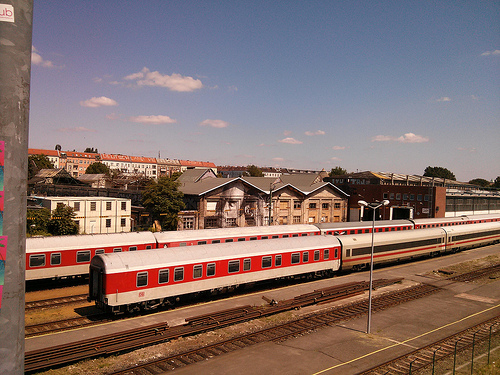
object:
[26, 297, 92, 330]
tracks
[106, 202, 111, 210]
window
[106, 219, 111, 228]
window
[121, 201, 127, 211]
window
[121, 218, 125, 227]
window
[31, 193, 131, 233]
building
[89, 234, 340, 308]
cabin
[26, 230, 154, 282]
cars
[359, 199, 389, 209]
street light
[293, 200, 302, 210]
window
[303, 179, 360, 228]
house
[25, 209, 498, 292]
train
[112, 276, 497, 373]
road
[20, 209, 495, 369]
station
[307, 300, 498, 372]
white line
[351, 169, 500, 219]
building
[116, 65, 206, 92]
clouds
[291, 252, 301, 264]
windows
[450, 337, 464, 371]
fence post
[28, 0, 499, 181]
sky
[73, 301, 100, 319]
shadow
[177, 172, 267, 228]
building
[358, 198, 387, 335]
pole light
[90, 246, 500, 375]
ground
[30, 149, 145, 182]
building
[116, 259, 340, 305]
stripe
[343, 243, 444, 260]
stripe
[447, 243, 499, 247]
stripe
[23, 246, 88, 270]
stripe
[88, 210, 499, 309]
train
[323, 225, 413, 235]
stripe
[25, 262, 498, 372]
tracks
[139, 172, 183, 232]
tree